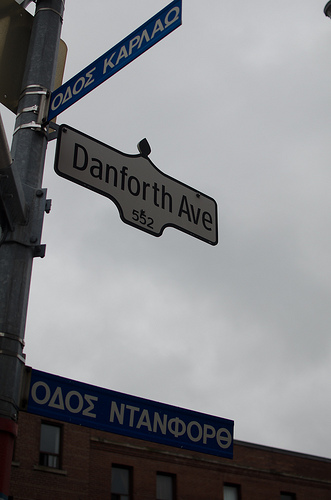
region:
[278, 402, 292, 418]
part of the cloud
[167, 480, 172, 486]
part of a window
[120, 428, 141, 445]
edge of a post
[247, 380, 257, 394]
part of the cloud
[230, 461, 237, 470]
part of a wall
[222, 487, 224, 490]
part of a window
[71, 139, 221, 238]
A black and white sign on pole.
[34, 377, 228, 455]
Blue sign on building.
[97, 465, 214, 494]
Building has windows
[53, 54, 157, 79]
Blue sign on the pole.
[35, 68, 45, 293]
Pole is tall and silver.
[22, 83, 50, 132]
Clasps to hold sign up.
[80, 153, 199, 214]
letters on sign is black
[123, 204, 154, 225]
552 on the sign.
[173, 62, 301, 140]
The sky is clear and blue.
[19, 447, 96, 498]
The building is made of bricks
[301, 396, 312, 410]
part of a cloud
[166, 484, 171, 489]
part of a window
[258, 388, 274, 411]
part of the cloud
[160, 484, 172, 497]
part of a window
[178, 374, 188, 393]
part of the cloud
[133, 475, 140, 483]
part of a window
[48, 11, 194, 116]
blue and white sign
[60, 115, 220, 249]
black and white sign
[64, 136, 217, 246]
black letters on sign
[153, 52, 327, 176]
sky is grey and dreary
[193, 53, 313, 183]
thick clouds in sky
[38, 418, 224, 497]
tall windows on building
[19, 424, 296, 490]
building is dark red brick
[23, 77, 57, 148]
metal connectors for signs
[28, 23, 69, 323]
signs on grey pole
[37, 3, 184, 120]
white letters on blue sign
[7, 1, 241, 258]
signs on a pole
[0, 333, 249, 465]
a sign on a pole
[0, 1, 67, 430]
a pole on side of building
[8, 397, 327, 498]
a building behind a pole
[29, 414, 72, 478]
a window of building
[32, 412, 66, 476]
a balcony on window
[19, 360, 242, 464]
letter of sign in foreign language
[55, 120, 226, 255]
a white sign with black letters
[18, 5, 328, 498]
it is an overcast day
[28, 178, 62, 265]
bolts on a pole